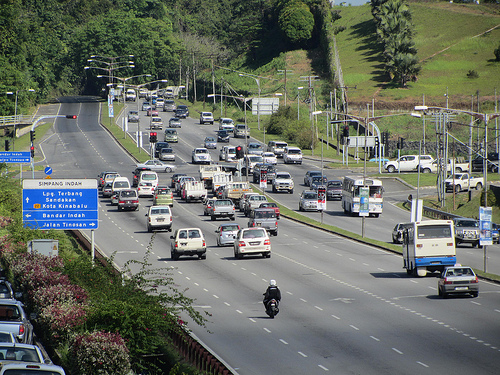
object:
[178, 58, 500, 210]
wall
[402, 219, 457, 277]
truck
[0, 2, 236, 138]
trees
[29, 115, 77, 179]
light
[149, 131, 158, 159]
signal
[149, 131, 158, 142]
light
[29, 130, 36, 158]
traffic light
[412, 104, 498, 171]
ground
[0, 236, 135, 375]
flowers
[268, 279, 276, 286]
helmet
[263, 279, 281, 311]
rider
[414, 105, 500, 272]
street light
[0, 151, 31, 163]
sign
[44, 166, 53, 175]
sign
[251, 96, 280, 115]
sign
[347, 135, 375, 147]
sign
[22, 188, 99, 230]
blue sign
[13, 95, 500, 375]
highway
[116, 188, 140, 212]
car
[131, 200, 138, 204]
light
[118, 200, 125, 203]
light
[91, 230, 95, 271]
pole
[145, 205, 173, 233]
car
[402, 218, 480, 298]
vehicles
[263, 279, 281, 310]
man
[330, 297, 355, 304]
arrow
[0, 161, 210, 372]
bush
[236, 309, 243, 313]
line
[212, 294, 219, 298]
line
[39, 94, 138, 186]
highway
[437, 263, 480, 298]
car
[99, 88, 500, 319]
traffic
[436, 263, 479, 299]
cars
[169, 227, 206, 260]
cars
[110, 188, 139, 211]
cars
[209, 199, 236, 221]
car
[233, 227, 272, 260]
car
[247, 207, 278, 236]
car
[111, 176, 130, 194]
car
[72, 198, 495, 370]
road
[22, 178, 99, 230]
blue/white sign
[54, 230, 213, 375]
bushes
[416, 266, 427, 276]
flap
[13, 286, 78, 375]
hedge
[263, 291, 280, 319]
motorcycle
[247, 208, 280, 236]
jeep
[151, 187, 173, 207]
jeep